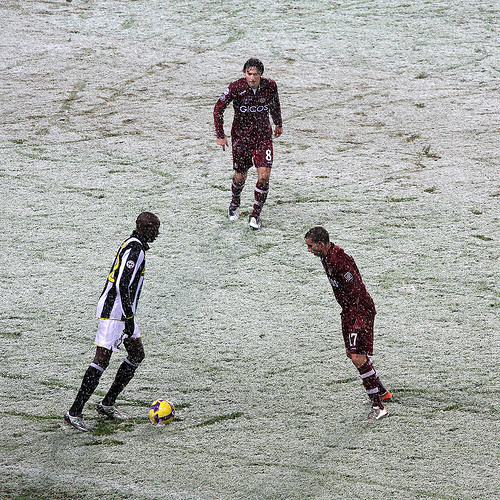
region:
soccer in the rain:
[41, 43, 418, 425]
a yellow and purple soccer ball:
[141, 356, 203, 433]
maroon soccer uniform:
[298, 223, 420, 435]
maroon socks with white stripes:
[331, 350, 418, 417]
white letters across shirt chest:
[236, 93, 278, 124]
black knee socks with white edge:
[66, 361, 145, 431]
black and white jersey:
[95, 223, 147, 320]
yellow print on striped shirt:
[97, 242, 144, 287]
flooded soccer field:
[32, 32, 489, 499]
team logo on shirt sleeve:
[216, 73, 235, 122]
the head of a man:
[289, 212, 371, 294]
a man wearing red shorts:
[317, 238, 396, 378]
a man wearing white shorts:
[48, 302, 155, 429]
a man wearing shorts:
[199, 114, 333, 176]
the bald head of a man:
[123, 200, 174, 247]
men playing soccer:
[51, 83, 479, 443]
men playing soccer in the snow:
[54, 128, 453, 462]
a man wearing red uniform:
[309, 208, 394, 450]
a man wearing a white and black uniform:
[65, 117, 220, 429]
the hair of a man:
[236, 39, 276, 99]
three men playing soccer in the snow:
[47, 40, 414, 455]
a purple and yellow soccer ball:
[144, 393, 181, 430]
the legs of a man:
[223, 153, 273, 228]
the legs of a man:
[65, 325, 150, 437]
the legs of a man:
[336, 324, 408, 424]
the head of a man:
[300, 219, 337, 258]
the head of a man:
[127, 205, 172, 244]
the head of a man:
[241, 58, 266, 88]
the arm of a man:
[111, 250, 141, 339]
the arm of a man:
[342, 256, 362, 338]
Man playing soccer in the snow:
[87, 201, 179, 426]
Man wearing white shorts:
[85, 310, 142, 351]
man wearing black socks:
[67, 363, 116, 407]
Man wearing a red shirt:
[225, 70, 283, 127]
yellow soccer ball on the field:
[155, 390, 190, 423]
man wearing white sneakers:
[228, 209, 268, 232]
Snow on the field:
[26, 59, 193, 197]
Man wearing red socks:
[226, 172, 277, 221]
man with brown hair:
[302, 218, 343, 248]